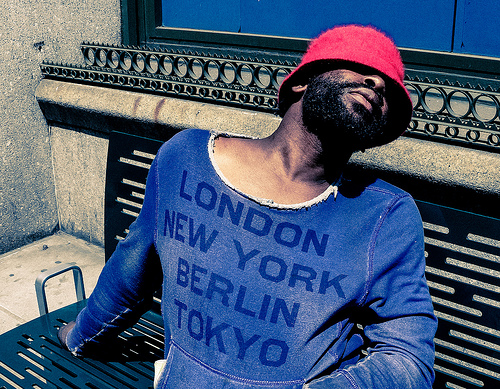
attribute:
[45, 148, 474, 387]
shirt — round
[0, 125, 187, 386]
bench — big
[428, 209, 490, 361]
street chair — black 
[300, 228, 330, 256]
lettering — blue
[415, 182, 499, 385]
street chair — black 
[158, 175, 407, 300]
lettering — blue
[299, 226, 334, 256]
lettering — blue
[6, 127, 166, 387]
bench — black 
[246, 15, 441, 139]
hat — red 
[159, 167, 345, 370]
lettering — blue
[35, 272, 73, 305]
handle — metal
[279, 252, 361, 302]
lettering — blue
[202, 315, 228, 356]
lettering — blue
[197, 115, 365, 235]
neck — large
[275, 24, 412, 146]
hat — red